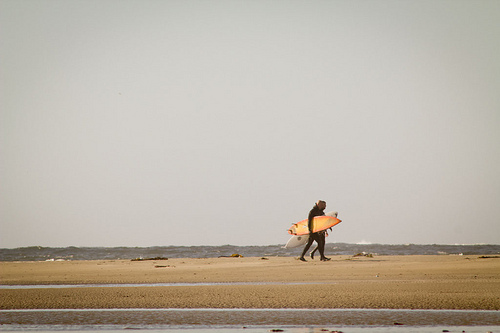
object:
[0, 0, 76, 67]
clouds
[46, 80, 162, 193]
overcast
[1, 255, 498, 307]
sand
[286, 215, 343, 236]
surfboard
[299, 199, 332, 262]
people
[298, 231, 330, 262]
legs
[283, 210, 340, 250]
surfboard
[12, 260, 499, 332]
beach sand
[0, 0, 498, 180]
sky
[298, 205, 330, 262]
black cloth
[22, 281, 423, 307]
ground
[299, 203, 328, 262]
wet suit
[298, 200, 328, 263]
man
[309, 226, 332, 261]
man